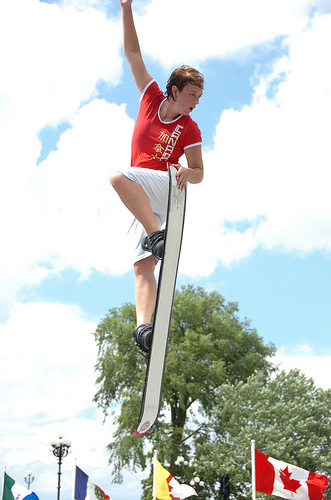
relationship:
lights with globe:
[46, 432, 70, 471] [64, 441, 70, 447]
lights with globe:
[46, 432, 70, 471] [59, 441, 66, 447]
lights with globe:
[46, 432, 70, 471] [50, 441, 60, 447]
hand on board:
[171, 163, 189, 191] [133, 159, 187, 437]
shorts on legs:
[106, 162, 204, 262] [102, 176, 171, 323]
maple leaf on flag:
[278, 466, 303, 493] [246, 439, 329, 497]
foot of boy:
[140, 227, 166, 262] [104, 31, 228, 228]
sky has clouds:
[255, 254, 329, 328] [2, 11, 114, 143]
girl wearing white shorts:
[108, 0, 205, 354] [134, 168, 168, 207]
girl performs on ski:
[108, 0, 205, 354] [134, 166, 187, 437]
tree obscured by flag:
[205, 366, 323, 498] [254, 445, 329, 498]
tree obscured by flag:
[91, 287, 248, 497] [156, 455, 203, 498]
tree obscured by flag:
[91, 287, 248, 497] [74, 469, 112, 498]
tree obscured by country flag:
[91, 287, 248, 497] [0, 467, 40, 500]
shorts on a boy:
[119, 167, 171, 266] [107, 1, 205, 356]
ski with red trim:
[134, 166, 187, 437] [126, 427, 153, 435]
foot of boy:
[128, 320, 153, 357] [107, 1, 205, 356]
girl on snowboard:
[108, 1, 205, 352] [136, 158, 188, 433]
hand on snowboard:
[171, 162, 189, 190] [155, 146, 185, 300]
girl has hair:
[108, 0, 205, 354] [164, 65, 203, 99]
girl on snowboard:
[108, 0, 205, 354] [144, 178, 203, 417]